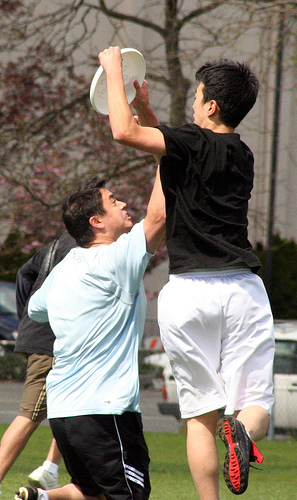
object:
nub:
[221, 422, 230, 428]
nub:
[223, 427, 228, 434]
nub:
[228, 450, 234, 455]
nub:
[228, 458, 236, 464]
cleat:
[247, 439, 263, 471]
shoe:
[215, 413, 262, 497]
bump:
[230, 466, 237, 471]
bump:
[230, 473, 236, 480]